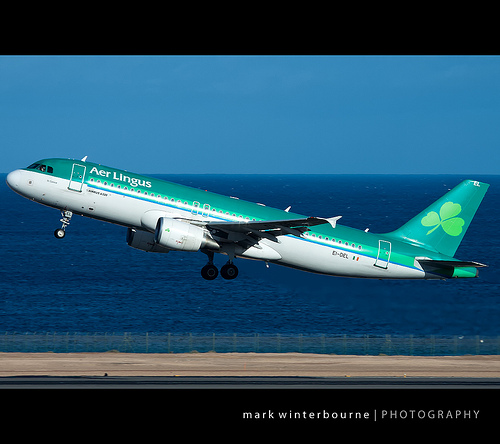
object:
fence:
[2, 333, 499, 356]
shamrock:
[414, 193, 467, 241]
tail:
[392, 180, 493, 284]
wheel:
[222, 262, 239, 279]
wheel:
[198, 264, 219, 280]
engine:
[152, 217, 226, 254]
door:
[374, 238, 392, 270]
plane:
[8, 156, 493, 286]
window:
[109, 182, 117, 188]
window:
[28, 162, 57, 174]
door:
[66, 162, 87, 194]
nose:
[4, 167, 20, 191]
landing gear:
[200, 250, 220, 281]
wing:
[142, 208, 342, 249]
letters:
[87, 165, 156, 191]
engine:
[124, 226, 172, 257]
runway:
[2, 349, 499, 387]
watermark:
[233, 401, 487, 427]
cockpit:
[23, 158, 61, 175]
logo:
[350, 255, 362, 262]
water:
[1, 237, 106, 333]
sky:
[1, 56, 499, 154]